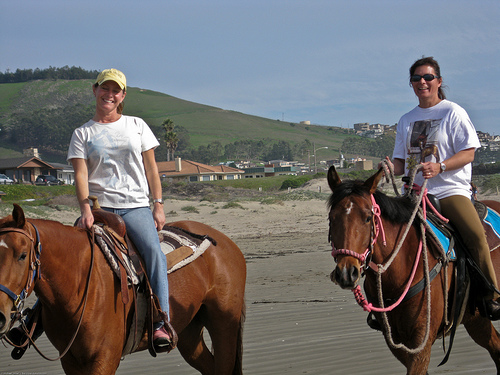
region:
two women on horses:
[2, 52, 497, 374]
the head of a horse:
[318, 162, 391, 291]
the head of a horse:
[0, 194, 40, 344]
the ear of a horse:
[323, 161, 343, 190]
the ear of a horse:
[367, 164, 384, 190]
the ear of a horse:
[10, 201, 25, 228]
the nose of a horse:
[331, 253, 363, 290]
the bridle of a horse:
[319, 245, 374, 317]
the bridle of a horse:
[0, 280, 36, 347]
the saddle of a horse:
[73, 191, 188, 283]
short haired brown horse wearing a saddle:
[0, 199, 256, 374]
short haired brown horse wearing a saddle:
[322, 157, 498, 372]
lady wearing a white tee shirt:
[66, 67, 182, 353]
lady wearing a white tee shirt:
[378, 49, 498, 325]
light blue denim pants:
[90, 200, 176, 335]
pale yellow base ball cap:
[92, 66, 126, 91]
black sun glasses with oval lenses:
[404, 70, 436, 82]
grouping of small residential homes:
[2, 143, 346, 195]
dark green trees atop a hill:
[0, 63, 347, 163]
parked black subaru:
[32, 172, 64, 189]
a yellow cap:
[91, 66, 126, 87]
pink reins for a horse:
[331, 185, 434, 317]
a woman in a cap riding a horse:
[0, 63, 257, 369]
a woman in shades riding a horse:
[321, 52, 498, 363]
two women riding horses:
[0, 53, 497, 372]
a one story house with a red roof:
[155, 156, 239, 184]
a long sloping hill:
[0, 70, 348, 152]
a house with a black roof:
[0, 152, 55, 184]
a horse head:
[318, 163, 385, 288]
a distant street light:
[311, 144, 329, 172]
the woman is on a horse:
[70, 63, 486, 330]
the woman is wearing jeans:
[90, 199, 225, 343]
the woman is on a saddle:
[72, 201, 191, 286]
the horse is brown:
[184, 268, 254, 330]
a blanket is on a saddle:
[128, 221, 251, 267]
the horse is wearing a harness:
[9, 225, 84, 371]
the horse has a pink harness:
[326, 181, 468, 368]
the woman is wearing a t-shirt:
[44, 110, 252, 270]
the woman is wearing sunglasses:
[405, 58, 477, 115]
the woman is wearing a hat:
[66, 56, 152, 96]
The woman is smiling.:
[63, 61, 180, 359]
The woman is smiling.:
[374, 56, 498, 325]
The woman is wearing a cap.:
[56, 54, 181, 355]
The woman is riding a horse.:
[1, 55, 254, 374]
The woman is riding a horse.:
[308, 45, 498, 374]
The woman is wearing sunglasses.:
[373, 50, 499, 334]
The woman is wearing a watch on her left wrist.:
[56, 59, 191, 354]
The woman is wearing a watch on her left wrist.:
[376, 53, 498, 374]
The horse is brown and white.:
[1, 198, 251, 373]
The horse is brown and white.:
[309, 157, 499, 373]